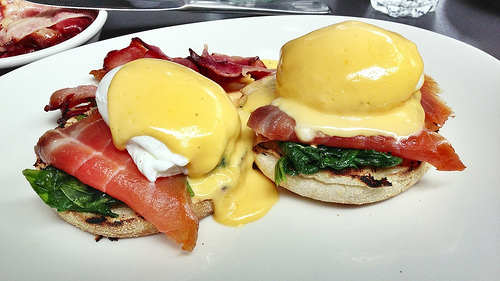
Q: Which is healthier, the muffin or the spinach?
A: The spinach is healthier than the muffin.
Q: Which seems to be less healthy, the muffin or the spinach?
A: The muffin is less healthy than the spinach.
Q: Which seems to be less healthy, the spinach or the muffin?
A: The muffin is less healthy than the spinach.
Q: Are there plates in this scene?
A: Yes, there is a plate.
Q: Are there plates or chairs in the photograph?
A: Yes, there is a plate.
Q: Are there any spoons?
A: No, there are no spoons.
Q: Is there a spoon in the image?
A: No, there are no spoons.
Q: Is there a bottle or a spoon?
A: No, there are no spoons or bottles.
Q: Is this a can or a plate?
A: This is a plate.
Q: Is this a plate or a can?
A: This is a plate.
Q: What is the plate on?
A: The plate is on the table.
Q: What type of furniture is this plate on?
A: The plate is on the table.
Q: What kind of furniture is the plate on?
A: The plate is on the table.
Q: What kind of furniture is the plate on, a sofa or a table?
A: The plate is on a table.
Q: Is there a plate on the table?
A: Yes, there is a plate on the table.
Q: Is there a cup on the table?
A: No, there is a plate on the table.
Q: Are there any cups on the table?
A: No, there is a plate on the table.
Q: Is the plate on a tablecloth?
A: No, the plate is on the table.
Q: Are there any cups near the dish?
A: No, there is a plate near the dish.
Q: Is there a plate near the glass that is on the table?
A: Yes, there is a plate near the glass.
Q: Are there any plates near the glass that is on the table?
A: Yes, there is a plate near the glass.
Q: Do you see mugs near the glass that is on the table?
A: No, there is a plate near the glass.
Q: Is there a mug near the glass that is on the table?
A: No, there is a plate near the glass.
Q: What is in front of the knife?
A: The plate is in front of the knife.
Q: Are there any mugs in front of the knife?
A: No, there is a plate in front of the knife.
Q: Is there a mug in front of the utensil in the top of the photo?
A: No, there is a plate in front of the knife.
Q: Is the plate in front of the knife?
A: Yes, the plate is in front of the knife.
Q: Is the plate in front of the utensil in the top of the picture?
A: Yes, the plate is in front of the knife.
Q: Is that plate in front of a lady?
A: No, the plate is in front of the knife.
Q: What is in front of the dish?
A: The plate is in front of the dish.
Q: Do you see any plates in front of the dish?
A: Yes, there is a plate in front of the dish.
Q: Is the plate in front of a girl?
A: No, the plate is in front of the dish.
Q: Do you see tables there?
A: Yes, there is a table.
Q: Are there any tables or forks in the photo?
A: Yes, there is a table.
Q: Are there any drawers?
A: No, there are no drawers.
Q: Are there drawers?
A: No, there are no drawers.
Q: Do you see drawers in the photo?
A: No, there are no drawers.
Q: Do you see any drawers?
A: No, there are no drawers.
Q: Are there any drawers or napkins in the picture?
A: No, there are no drawers or napkins.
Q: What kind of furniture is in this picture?
A: The furniture is a table.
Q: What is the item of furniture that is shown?
A: The piece of furniture is a table.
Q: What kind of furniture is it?
A: The piece of furniture is a table.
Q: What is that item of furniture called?
A: This is a table.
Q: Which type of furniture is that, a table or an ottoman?
A: This is a table.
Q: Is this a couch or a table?
A: This is a table.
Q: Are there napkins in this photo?
A: No, there are no napkins.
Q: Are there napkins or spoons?
A: No, there are no napkins or spoons.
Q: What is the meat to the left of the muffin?
A: The meat is ham.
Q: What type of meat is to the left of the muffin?
A: The meat is ham.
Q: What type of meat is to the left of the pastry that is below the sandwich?
A: The meat is ham.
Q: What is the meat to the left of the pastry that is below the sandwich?
A: The meat is ham.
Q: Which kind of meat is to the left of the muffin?
A: The meat is ham.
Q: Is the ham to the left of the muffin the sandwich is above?
A: Yes, the ham is to the left of the muffin.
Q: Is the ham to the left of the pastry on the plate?
A: Yes, the ham is to the left of the muffin.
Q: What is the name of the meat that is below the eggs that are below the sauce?
A: The meat is ham.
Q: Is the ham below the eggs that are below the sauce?
A: Yes, the ham is below the eggs.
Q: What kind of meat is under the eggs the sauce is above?
A: The meat is ham.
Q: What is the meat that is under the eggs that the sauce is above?
A: The meat is ham.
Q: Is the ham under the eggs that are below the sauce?
A: Yes, the ham is under the eggs.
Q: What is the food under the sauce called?
A: The food is eggs.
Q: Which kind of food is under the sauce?
A: The food is eggs.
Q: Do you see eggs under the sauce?
A: Yes, there are eggs under the sauce.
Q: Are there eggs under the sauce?
A: Yes, there are eggs under the sauce.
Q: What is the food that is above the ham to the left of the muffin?
A: The food is eggs.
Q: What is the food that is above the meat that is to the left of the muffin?
A: The food is eggs.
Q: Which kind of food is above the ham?
A: The food is eggs.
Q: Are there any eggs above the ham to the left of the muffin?
A: Yes, there are eggs above the ham.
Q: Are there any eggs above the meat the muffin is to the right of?
A: Yes, there are eggs above the ham.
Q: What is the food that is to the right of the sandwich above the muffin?
A: The food is eggs.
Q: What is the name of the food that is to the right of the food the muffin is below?
A: The food is eggs.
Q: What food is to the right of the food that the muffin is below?
A: The food is eggs.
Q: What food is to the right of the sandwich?
A: The food is eggs.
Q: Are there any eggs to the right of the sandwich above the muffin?
A: Yes, there are eggs to the right of the sandwich.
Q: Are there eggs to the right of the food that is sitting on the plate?
A: Yes, there are eggs to the right of the sandwich.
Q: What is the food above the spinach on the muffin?
A: The food is eggs.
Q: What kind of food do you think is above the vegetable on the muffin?
A: The food is eggs.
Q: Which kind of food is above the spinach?
A: The food is eggs.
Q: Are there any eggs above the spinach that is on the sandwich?
A: Yes, there are eggs above the spinach.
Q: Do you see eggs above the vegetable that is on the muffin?
A: Yes, there are eggs above the spinach.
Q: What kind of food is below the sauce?
A: The food is eggs.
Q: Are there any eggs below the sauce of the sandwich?
A: Yes, there are eggs below the sauce.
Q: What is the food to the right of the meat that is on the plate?
A: The food is eggs.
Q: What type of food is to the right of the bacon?
A: The food is eggs.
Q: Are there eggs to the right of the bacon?
A: Yes, there are eggs to the right of the bacon.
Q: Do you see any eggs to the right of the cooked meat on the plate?
A: Yes, there are eggs to the right of the bacon.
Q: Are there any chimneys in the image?
A: No, there are no chimneys.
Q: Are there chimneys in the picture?
A: No, there are no chimneys.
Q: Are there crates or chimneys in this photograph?
A: No, there are no chimneys or crates.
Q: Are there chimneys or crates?
A: No, there are no chimneys or crates.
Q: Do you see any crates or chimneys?
A: No, there are no chimneys or crates.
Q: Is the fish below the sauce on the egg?
A: Yes, the fish is below the sauce.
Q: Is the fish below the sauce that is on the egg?
A: Yes, the fish is below the sauce.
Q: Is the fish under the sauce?
A: Yes, the fish is under the sauce.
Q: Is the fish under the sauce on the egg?
A: Yes, the fish is under the sauce.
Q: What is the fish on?
A: The fish is on the muffin.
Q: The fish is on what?
A: The fish is on the muffin.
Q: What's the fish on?
A: The fish is on the muffin.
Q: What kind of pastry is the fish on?
A: The fish is on the muffin.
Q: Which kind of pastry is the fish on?
A: The fish is on the muffin.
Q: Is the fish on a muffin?
A: Yes, the fish is on a muffin.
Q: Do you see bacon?
A: Yes, there is bacon.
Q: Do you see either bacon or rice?
A: Yes, there is bacon.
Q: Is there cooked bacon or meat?
A: Yes, there is cooked bacon.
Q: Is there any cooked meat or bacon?
A: Yes, there is cooked bacon.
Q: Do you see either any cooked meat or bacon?
A: Yes, there is cooked bacon.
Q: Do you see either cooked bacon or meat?
A: Yes, there is cooked bacon.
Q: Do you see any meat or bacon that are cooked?
A: Yes, the bacon is cooked.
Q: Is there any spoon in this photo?
A: No, there are no spoons.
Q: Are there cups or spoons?
A: No, there are no spoons or cups.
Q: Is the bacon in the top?
A: Yes, the bacon is in the top of the image.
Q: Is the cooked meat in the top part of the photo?
A: Yes, the bacon is in the top of the image.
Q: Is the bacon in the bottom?
A: No, the bacon is in the top of the image.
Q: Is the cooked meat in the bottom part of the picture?
A: No, the bacon is in the top of the image.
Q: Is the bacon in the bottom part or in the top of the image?
A: The bacon is in the top of the image.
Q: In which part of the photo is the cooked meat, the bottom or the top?
A: The bacon is in the top of the image.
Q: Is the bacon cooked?
A: Yes, the bacon is cooked.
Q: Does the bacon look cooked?
A: Yes, the bacon is cooked.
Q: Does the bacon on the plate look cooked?
A: Yes, the bacon is cooked.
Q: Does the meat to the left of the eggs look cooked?
A: Yes, the bacon is cooked.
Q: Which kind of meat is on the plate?
A: The meat is bacon.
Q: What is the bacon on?
A: The bacon is on the plate.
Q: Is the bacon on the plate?
A: Yes, the bacon is on the plate.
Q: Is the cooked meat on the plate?
A: Yes, the bacon is on the plate.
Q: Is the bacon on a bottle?
A: No, the bacon is on the plate.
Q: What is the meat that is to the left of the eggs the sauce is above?
A: The meat is bacon.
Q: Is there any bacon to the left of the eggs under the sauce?
A: Yes, there is bacon to the left of the eggs.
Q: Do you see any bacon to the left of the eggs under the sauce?
A: Yes, there is bacon to the left of the eggs.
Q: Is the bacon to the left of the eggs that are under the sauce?
A: Yes, the bacon is to the left of the eggs.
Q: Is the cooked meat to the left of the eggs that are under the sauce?
A: Yes, the bacon is to the left of the eggs.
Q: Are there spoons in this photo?
A: No, there are no spoons.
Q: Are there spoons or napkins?
A: No, there are no spoons or napkins.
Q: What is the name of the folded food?
A: The food is an egg.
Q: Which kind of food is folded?
A: The food is an egg.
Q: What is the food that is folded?
A: The food is an egg.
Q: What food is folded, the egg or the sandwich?
A: The egg is folded.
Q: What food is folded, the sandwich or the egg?
A: The egg is folded.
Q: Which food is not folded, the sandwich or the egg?
A: The sandwich is not folded.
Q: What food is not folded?
A: The food is a sandwich.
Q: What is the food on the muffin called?
A: The food is an egg.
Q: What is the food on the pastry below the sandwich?
A: The food is an egg.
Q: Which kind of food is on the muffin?
A: The food is an egg.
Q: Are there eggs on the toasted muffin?
A: Yes, there is an egg on the muffin.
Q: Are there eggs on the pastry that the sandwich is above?
A: Yes, there is an egg on the muffin.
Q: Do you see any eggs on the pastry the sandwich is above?
A: Yes, there is an egg on the muffin.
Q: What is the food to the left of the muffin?
A: The food is an egg.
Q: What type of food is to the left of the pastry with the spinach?
A: The food is an egg.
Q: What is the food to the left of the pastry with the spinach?
A: The food is an egg.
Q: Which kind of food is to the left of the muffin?
A: The food is an egg.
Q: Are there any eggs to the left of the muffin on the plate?
A: Yes, there is an egg to the left of the muffin.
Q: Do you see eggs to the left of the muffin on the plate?
A: Yes, there is an egg to the left of the muffin.